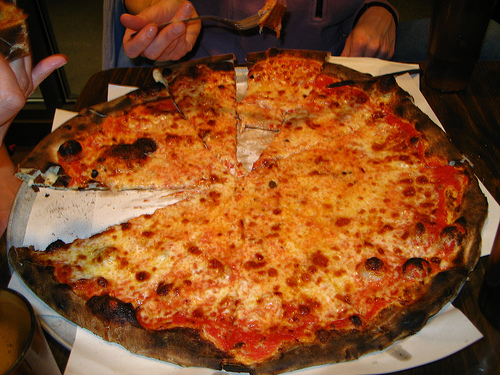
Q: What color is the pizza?
A: The pizza is orange.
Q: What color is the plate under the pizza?
A: The plate is white.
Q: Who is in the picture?
A: Two people are in the picture.